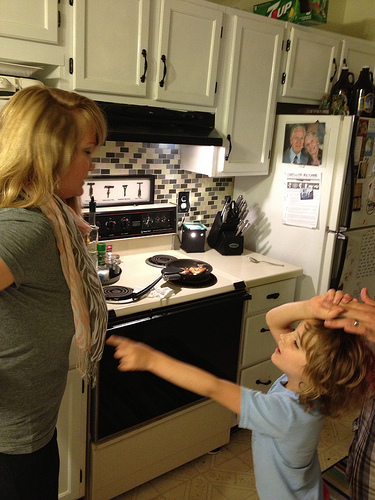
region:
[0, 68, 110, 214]
a woman with blonde hair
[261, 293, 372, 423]
a child with blonde hair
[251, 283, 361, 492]
a boy wearing a blue shirt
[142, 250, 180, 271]
a burner on a stove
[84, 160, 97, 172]
the nose of a woman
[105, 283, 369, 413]
a boy pointing at his mother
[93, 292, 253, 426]
the door of an oven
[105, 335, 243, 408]
the arm of a boy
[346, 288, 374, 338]
a hand wearing a wedding ring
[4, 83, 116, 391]
a woman wearing a scarf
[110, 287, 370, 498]
A young boy points at someone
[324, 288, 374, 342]
A woman's hand holds the hand of the boy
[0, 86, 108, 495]
A woman wearing a scarf stands in the kitchen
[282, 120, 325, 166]
A picture of an older couple posted on the fridge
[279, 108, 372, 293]
A white refrigerator stands in the kitchen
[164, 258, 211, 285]
A frying pan with food in it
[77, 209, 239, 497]
A black and white stove in the kitchen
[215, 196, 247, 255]
A collection of knives sits next to the stove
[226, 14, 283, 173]
A long white kitchen cabinet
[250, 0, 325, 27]
A box of 7up cans sits on the cabinets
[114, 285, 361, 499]
the kid pointing towards the woman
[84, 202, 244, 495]
the stove and oven sitting in the kitchen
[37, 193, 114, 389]
the scarf the woman is wearing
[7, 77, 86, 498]
the woman standing by the oven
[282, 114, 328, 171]
a picture of an older couple on the fridge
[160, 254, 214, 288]
a pan sitting on the oven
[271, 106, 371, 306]
a fridge covered in assorted photos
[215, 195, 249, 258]
a knife block filled with white handled knives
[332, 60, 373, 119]
bottles sitting on top of the fridge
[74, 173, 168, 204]
a picture on top of the stove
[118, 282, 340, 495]
small child pointing to a woman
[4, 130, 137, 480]
a woman wearing two scarves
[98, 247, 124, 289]
different spices sitting on a tray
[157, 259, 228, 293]
a frying pan sitting on the stove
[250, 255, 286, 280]
a spoon sitting on the counter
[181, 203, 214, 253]
a black and silver toaster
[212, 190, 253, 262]
a set of kitchen knives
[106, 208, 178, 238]
control knobs of a stove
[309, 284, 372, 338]
little boy hoilding hands on top of his head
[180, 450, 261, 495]
decorative floor tile